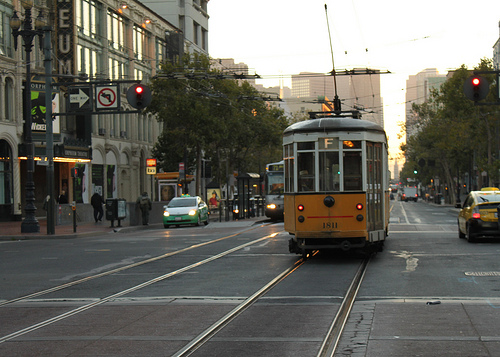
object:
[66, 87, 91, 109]
street signs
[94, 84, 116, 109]
street signs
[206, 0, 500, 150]
sky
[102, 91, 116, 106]
arrow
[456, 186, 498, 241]
cab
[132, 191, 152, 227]
people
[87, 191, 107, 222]
people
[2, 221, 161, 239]
sidewalk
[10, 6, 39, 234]
pole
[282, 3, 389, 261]
trolley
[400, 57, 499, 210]
trees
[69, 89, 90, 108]
arrow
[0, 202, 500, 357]
asphalt surface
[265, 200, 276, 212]
yellow light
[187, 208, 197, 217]
yellow light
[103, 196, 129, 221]
newspaper box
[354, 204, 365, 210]
light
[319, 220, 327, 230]
number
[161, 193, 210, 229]
cab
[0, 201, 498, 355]
road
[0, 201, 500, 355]
surface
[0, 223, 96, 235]
surface